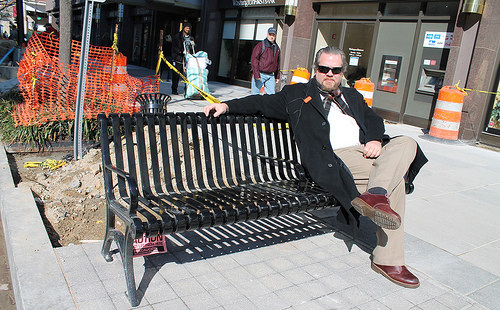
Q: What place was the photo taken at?
A: It was taken at the pavement.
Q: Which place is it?
A: It is a pavement.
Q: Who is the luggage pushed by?
A: The luggage is pushed by the man.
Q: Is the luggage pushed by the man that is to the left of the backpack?
A: Yes, the luggage is pushed by the man.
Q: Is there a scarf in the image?
A: Yes, there is a scarf.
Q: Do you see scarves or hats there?
A: Yes, there is a scarf.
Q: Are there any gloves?
A: No, there are no gloves.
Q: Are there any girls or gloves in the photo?
A: No, there are no gloves or girls.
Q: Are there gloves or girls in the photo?
A: No, there are no gloves or girls.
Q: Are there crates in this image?
A: No, there are no crates.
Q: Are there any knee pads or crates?
A: No, there are no crates or knee pads.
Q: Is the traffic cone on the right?
A: Yes, the traffic cone is on the right of the image.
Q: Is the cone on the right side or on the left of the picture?
A: The cone is on the right of the image.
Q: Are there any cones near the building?
A: Yes, there is a cone near the building.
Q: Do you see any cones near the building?
A: Yes, there is a cone near the building.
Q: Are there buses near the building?
A: No, there is a cone near the building.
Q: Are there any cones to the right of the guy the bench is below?
A: Yes, there is a cone to the right of the guy.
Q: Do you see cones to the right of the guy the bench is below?
A: Yes, there is a cone to the right of the guy.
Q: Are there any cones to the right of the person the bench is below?
A: Yes, there is a cone to the right of the guy.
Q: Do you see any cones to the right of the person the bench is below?
A: Yes, there is a cone to the right of the guy.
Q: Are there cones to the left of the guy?
A: No, the cone is to the right of the guy.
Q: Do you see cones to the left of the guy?
A: No, the cone is to the right of the guy.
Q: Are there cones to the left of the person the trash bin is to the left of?
A: No, the cone is to the right of the guy.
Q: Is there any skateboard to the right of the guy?
A: No, there is a cone to the right of the guy.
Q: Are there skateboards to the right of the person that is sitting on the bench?
A: No, there is a cone to the right of the guy.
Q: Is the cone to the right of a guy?
A: Yes, the cone is to the right of a guy.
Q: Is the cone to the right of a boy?
A: No, the cone is to the right of a guy.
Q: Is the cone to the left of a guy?
A: No, the cone is to the right of a guy.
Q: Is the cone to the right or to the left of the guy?
A: The cone is to the right of the guy.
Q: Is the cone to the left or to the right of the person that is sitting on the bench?
A: The cone is to the right of the guy.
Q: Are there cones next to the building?
A: Yes, there is a cone next to the building.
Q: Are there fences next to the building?
A: No, there is a cone next to the building.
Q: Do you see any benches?
A: Yes, there is a bench.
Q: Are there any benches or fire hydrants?
A: Yes, there is a bench.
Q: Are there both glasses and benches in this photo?
A: Yes, there are both a bench and glasses.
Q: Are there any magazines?
A: No, there are no magazines.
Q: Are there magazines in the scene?
A: No, there are no magazines.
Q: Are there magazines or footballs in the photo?
A: No, there are no magazines or footballs.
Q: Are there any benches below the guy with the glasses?
A: Yes, there is a bench below the guy.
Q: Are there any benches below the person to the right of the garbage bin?
A: Yes, there is a bench below the guy.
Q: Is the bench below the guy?
A: Yes, the bench is below the guy.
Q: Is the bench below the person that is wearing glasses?
A: Yes, the bench is below the guy.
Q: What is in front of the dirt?
A: The bench is in front of the dirt.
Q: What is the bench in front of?
A: The bench is in front of the dirt.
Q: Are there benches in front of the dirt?
A: Yes, there is a bench in front of the dirt.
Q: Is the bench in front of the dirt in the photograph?
A: Yes, the bench is in front of the dirt.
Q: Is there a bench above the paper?
A: Yes, there is a bench above the paper.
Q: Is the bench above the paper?
A: Yes, the bench is above the paper.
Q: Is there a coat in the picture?
A: Yes, there is a coat.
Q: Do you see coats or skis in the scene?
A: Yes, there is a coat.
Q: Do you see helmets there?
A: No, there are no helmets.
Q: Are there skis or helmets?
A: No, there are no helmets or skis.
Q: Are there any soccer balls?
A: No, there are no soccer balls.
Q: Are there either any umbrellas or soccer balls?
A: No, there are no soccer balls or umbrellas.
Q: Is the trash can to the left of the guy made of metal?
A: Yes, the garbage can is made of metal.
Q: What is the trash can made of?
A: The trash can is made of metal.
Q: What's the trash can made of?
A: The trash can is made of metal.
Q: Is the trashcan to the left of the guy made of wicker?
A: No, the trash can is made of metal.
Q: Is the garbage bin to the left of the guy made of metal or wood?
A: The trash can is made of metal.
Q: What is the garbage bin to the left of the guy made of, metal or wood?
A: The trash can is made of metal.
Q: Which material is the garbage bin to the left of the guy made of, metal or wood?
A: The trash can is made of metal.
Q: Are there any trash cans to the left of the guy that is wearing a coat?
A: Yes, there is a trash can to the left of the guy.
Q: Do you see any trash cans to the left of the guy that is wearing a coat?
A: Yes, there is a trash can to the left of the guy.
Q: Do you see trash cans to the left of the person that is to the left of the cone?
A: Yes, there is a trash can to the left of the guy.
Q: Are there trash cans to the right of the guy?
A: No, the trash can is to the left of the guy.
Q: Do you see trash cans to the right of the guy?
A: No, the trash can is to the left of the guy.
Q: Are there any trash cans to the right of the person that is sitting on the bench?
A: No, the trash can is to the left of the guy.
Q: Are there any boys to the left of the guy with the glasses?
A: No, there is a trash can to the left of the guy.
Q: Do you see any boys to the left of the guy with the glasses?
A: No, there is a trash can to the left of the guy.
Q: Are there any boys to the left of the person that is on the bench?
A: No, there is a trash can to the left of the guy.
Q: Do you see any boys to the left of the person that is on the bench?
A: No, there is a trash can to the left of the guy.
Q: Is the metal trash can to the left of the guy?
A: Yes, the trash can is to the left of the guy.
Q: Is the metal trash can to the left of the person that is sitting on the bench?
A: Yes, the trash can is to the left of the guy.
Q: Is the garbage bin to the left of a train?
A: No, the garbage bin is to the left of the guy.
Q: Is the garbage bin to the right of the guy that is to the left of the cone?
A: No, the garbage bin is to the left of the guy.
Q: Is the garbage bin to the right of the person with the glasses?
A: No, the garbage bin is to the left of the guy.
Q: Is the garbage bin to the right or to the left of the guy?
A: The garbage bin is to the left of the guy.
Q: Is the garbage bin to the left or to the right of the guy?
A: The garbage bin is to the left of the guy.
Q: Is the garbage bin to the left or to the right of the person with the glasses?
A: The garbage bin is to the left of the guy.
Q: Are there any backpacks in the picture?
A: Yes, there is a backpack.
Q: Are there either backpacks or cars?
A: Yes, there is a backpack.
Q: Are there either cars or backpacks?
A: Yes, there is a backpack.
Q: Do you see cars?
A: No, there are no cars.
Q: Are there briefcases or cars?
A: No, there are no cars or briefcases.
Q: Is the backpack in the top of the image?
A: Yes, the backpack is in the top of the image.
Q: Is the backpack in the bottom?
A: No, the backpack is in the top of the image.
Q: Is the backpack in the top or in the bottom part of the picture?
A: The backpack is in the top of the image.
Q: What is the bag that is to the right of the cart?
A: The bag is a backpack.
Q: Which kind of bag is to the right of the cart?
A: The bag is a backpack.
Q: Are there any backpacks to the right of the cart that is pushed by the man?
A: Yes, there is a backpack to the right of the cart.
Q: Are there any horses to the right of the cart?
A: No, there is a backpack to the right of the cart.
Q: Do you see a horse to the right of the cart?
A: No, there is a backpack to the right of the cart.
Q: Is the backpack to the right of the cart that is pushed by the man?
A: Yes, the backpack is to the right of the cart.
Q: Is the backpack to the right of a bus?
A: No, the backpack is to the right of the cart.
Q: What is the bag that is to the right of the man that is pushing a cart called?
A: The bag is a backpack.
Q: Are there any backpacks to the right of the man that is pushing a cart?
A: Yes, there is a backpack to the right of the man.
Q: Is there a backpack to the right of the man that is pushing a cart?
A: Yes, there is a backpack to the right of the man.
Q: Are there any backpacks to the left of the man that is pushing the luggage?
A: No, the backpack is to the right of the man.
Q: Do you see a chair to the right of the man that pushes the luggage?
A: No, there is a backpack to the right of the man.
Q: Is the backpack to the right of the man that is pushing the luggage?
A: Yes, the backpack is to the right of the man.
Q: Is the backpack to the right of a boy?
A: No, the backpack is to the right of the man.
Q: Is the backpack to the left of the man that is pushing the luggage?
A: No, the backpack is to the right of the man.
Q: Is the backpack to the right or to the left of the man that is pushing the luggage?
A: The backpack is to the right of the man.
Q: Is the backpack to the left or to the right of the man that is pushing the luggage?
A: The backpack is to the right of the man.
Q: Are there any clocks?
A: No, there are no clocks.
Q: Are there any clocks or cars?
A: No, there are no clocks or cars.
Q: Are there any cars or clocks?
A: No, there are no clocks or cars.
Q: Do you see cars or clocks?
A: No, there are no clocks or cars.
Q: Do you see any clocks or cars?
A: No, there are no clocks or cars.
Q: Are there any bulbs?
A: No, there are no bulbs.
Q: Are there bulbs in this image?
A: No, there are no bulbs.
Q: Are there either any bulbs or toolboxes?
A: No, there are no bulbs or toolboxes.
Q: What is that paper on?
A: The paper is on the bench.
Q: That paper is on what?
A: The paper is on the bench.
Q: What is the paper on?
A: The paper is on the bench.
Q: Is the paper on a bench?
A: Yes, the paper is on a bench.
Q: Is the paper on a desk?
A: No, the paper is on a bench.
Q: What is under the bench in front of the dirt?
A: The paper is under the bench.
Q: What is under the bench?
A: The paper is under the bench.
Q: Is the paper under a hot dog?
A: No, the paper is under the bench.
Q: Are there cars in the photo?
A: No, there are no cars.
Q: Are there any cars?
A: No, there are no cars.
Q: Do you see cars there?
A: No, there are no cars.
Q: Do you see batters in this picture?
A: No, there are no batters.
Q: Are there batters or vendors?
A: No, there are no batters or vendors.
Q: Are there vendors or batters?
A: No, there are no batters or vendors.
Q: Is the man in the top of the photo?
A: Yes, the man is in the top of the image.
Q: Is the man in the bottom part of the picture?
A: No, the man is in the top of the image.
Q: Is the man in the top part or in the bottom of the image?
A: The man is in the top of the image.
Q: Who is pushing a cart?
A: The man is pushing a cart.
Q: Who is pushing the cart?
A: The man is pushing a cart.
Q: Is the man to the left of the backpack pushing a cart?
A: Yes, the man is pushing a cart.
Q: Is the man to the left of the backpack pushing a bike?
A: No, the man is pushing a cart.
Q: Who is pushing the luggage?
A: The man is pushing the luggage.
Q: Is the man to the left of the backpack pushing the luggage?
A: Yes, the man is pushing the luggage.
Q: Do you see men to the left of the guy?
A: Yes, there is a man to the left of the guy.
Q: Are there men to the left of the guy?
A: Yes, there is a man to the left of the guy.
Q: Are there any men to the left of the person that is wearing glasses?
A: Yes, there is a man to the left of the guy.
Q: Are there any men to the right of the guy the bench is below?
A: No, the man is to the left of the guy.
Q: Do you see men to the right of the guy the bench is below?
A: No, the man is to the left of the guy.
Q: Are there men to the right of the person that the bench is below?
A: No, the man is to the left of the guy.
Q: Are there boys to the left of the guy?
A: No, there is a man to the left of the guy.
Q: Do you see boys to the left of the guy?
A: No, there is a man to the left of the guy.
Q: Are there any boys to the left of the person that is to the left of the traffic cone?
A: No, there is a man to the left of the guy.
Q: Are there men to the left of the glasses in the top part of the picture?
A: Yes, there is a man to the left of the glasses.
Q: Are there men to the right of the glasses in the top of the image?
A: No, the man is to the left of the glasses.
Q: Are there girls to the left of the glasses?
A: No, there is a man to the left of the glasses.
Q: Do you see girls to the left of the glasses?
A: No, there is a man to the left of the glasses.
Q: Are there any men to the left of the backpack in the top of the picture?
A: Yes, there is a man to the left of the backpack.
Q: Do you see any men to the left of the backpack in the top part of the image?
A: Yes, there is a man to the left of the backpack.